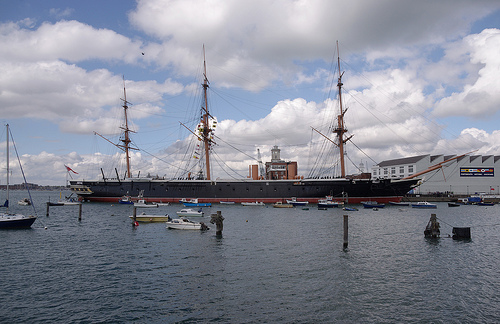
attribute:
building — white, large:
[375, 152, 500, 196]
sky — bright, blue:
[0, 0, 499, 188]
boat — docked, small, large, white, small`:
[166, 217, 202, 229]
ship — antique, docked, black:
[54, 45, 482, 212]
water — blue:
[6, 185, 499, 314]